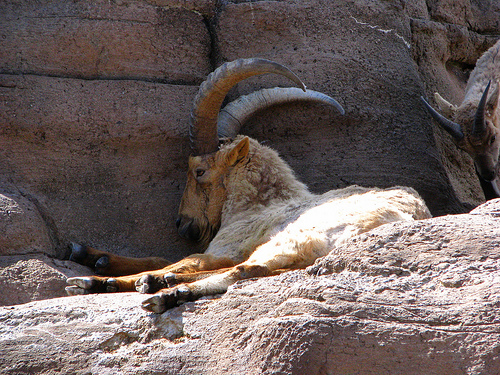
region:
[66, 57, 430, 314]
horned animal on a rock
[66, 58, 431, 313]
an animal seeking the shade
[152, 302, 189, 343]
the shadow of the rear foot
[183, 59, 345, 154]
horns of the animal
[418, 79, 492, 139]
a pair of shorter horns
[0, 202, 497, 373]
the weathered face of a cliff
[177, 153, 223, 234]
the left face of the goat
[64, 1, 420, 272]
shaded part of the animal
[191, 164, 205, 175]
the left eye of the animal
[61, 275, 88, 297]
cloven hoof of the animal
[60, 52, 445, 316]
Ram laying on the rock.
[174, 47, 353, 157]
Horns on the ram's head.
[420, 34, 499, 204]
Gazelle on the rock.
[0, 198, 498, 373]
Ledge on the rocks.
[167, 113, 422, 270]
White fur on ram.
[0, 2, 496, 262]
Rock wall in the background.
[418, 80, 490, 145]
black horns on gazelle.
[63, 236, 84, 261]
Gray hoof on the ram.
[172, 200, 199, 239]
Brown nose on the ram.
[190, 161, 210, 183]
brown eye on the ram.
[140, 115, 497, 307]
A yak is in the mountains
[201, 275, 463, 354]
Teh mountains are beige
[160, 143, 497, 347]
The yak is tan colored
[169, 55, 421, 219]
The yak has two horns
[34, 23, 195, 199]
The mountains are behind the yak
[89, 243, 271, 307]
The yak has brown legs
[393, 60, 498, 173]
There are crakcs in the mountains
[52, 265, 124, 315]
The yak has nails on his hoofs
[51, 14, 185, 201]
The mountains have several layers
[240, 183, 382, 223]
The sun is shining on the yak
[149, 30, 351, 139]
curved horns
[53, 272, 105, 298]
hooves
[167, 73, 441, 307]
horned animal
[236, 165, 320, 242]
tan fur on animal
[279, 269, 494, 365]
grooves on rock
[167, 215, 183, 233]
black colored nostrils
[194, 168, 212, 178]
yellow colored eyes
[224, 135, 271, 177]
pointy shaped ears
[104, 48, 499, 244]
two furry animals with fur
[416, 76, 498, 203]
horned animal on cliff with head down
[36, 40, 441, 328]
a ram in a zoo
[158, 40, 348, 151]
the horns of a ram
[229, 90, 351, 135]
the horn of a ram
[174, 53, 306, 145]
the horn of a ram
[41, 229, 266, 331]
the four legs of a ram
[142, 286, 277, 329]
the leg of a ram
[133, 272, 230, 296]
the leg of a ram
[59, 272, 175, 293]
the leg of a ram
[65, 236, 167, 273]
the leg of a ram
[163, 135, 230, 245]
the head of a ram